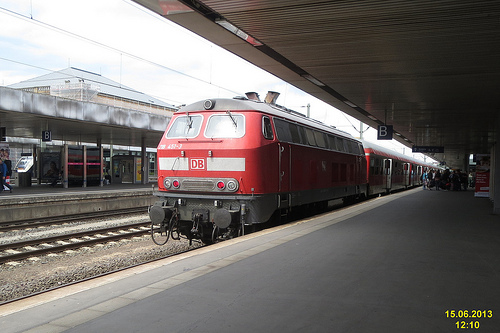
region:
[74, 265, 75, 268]
part of a rock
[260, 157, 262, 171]
edge of a train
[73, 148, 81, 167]
part of a window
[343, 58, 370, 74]
part of a roof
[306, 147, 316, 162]
part of a train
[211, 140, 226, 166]
part of a window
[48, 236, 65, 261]
part of a rail way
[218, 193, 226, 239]
part of a steel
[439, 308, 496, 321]
Date photo was taken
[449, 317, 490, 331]
Time photo was taken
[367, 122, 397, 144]
Train platform identification sign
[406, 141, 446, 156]
Train station identification sign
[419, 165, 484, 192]
People boarding and leaving train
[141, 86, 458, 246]
Passenger train at station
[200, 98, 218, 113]
Sounding horn of train engine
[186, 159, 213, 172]
Train engine owner identification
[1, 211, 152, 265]
Metal train rails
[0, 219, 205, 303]
Gravel covered ground between train rails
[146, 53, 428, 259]
RED TRAIN AT STATION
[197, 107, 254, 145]
GLASS WINDSHIELD ON TRAIN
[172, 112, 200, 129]
GLASS WINDSHIELD ON TRAIN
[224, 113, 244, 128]
BLACK WINDSHIELD WIPER ON TRAIN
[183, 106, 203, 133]
BLACK WINDSHIELD WIPER ON TRAIN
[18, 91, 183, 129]
STAINED ROOF OF STATION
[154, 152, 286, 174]
WHITE LINE ON FRONT OF TRAIN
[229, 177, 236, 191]
ROUND HEADLIGHT ON TRAIN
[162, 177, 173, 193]
ROUND HEADLIGHT ON TRAIN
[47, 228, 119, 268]
METAL RAILS ON GROUND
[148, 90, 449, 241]
Red train stopped in the terminal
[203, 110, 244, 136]
Left front windshield of red train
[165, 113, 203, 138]
Right front windshield of red train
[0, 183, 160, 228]
Train platform across from the red train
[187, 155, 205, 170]
Red letter and number on the front of the train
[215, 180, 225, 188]
Left red light on the front of the train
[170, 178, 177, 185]
Right red light of the red train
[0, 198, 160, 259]
Railroad tracks between the red train and the platform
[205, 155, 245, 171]
White patch on the left front of the train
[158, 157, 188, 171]
White patch on the right front of the red train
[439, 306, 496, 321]
Date photograph was taken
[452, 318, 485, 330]
Time photograph was taken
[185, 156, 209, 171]
Train owner identification letters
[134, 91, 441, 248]
Red passenger train at station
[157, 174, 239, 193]
Headlights on passenger train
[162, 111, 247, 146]
Dual windshields on train engine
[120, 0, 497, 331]
Covered train platform